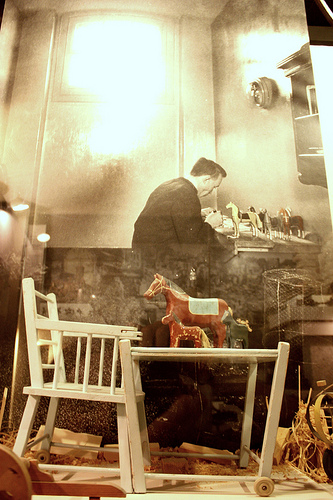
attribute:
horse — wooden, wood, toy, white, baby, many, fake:
[134, 274, 243, 362]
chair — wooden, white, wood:
[24, 285, 149, 456]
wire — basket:
[244, 389, 323, 454]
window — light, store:
[268, 93, 315, 183]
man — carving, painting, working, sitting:
[132, 132, 274, 278]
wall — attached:
[20, 145, 156, 263]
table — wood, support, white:
[202, 209, 314, 340]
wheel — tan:
[262, 359, 306, 378]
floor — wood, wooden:
[181, 446, 250, 498]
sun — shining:
[138, 48, 256, 128]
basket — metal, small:
[247, 417, 330, 469]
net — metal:
[293, 397, 327, 431]